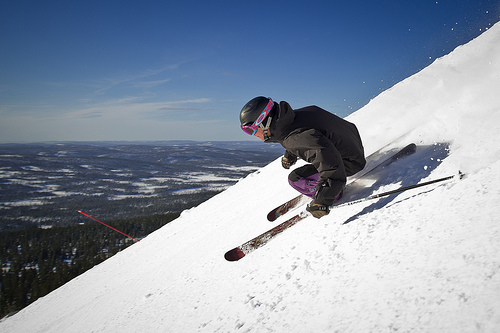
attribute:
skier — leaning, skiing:
[223, 89, 365, 226]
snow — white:
[10, 25, 498, 331]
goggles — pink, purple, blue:
[240, 97, 278, 141]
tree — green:
[34, 248, 49, 272]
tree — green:
[8, 255, 24, 276]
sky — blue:
[3, 5, 493, 145]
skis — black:
[220, 143, 431, 262]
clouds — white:
[64, 91, 215, 129]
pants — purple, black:
[287, 166, 347, 208]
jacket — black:
[269, 101, 373, 201]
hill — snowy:
[14, 77, 499, 314]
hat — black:
[242, 96, 277, 128]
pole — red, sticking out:
[73, 208, 148, 250]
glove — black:
[305, 203, 336, 220]